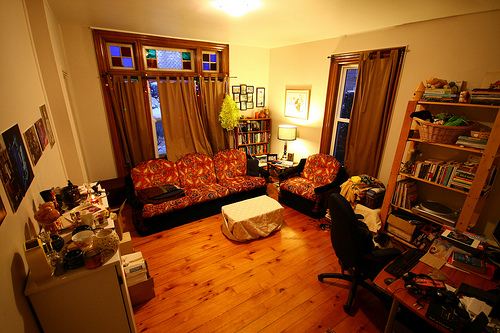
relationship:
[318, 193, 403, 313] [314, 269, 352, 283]
chair has foot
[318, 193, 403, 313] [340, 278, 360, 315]
chair has foot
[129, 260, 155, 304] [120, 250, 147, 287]
box filled with papers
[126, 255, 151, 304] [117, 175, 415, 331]
box on floor